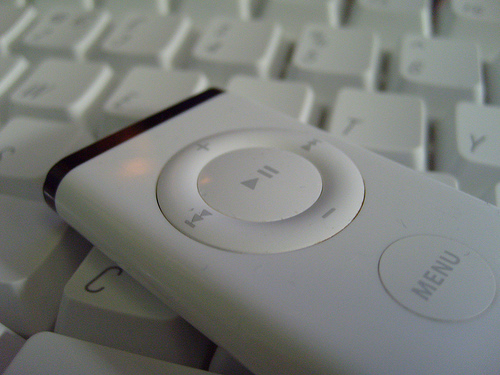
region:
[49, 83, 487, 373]
White remote control on keyboard.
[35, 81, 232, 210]
Black top of remote control.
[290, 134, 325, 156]
Fast forward arrow of remote control.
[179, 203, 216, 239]
Rewind arrows of remote control.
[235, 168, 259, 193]
Single arrow in center of remote control.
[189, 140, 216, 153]
Plus sign on remote control.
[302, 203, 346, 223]
Minus sign on remote control.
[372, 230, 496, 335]
Menu button of remote control.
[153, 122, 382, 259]
One white circle with a round button in its center.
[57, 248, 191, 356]
The letter 'C' in black.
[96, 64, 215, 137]
key button on keyboard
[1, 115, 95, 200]
key button on keyboard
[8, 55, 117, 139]
key button on keyboard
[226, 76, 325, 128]
key button on keyboard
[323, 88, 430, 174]
key button on keyboard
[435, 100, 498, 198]
key button on keyboard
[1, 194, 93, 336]
key button on keyboard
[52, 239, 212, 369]
key button on keyboard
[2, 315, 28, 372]
key button on keyboard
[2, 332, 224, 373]
key button on keyboard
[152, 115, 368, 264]
directional buttons that are round and white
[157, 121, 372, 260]
round and white buttons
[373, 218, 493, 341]
button with the word menu on it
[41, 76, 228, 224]
black area on remote control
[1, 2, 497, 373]
white keyboard with remote on top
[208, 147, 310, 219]
play button in center of remote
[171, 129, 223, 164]
plus button on remote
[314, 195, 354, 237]
minus button on remote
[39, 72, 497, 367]
remote control on top of keyboard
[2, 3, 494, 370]
black and white remote on top of keyboard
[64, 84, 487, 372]
a white ipod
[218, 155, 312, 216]
the play button on the ipod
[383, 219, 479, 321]
the menu button on the ipod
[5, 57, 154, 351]
a white keyboard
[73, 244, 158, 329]
a button on the keyboard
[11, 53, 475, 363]
a white ipod on a white keyboard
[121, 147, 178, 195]
an orange light on the ipod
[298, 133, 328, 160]
the next button on the ipod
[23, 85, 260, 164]
the black tip of the ipod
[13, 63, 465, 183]
buttons on the keyboard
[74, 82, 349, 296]
an apple remote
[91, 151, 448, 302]
the remote is white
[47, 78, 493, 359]
the remote is on the keyboard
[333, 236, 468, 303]
the menu button is on the keyboard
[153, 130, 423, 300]
the play button is on the remote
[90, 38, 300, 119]
the keyboard has black writing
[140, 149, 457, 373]
the remote has gray writing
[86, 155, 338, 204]
a light is in the remote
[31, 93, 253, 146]
a black tip is on the remote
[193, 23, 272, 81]
letters and numbers are on the keys